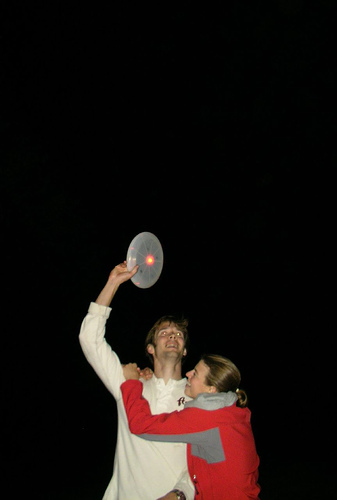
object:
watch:
[169, 486, 185, 499]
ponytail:
[235, 386, 250, 410]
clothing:
[119, 377, 262, 499]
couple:
[55, 254, 265, 500]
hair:
[201, 354, 247, 409]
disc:
[125, 230, 164, 289]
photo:
[0, 2, 336, 500]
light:
[146, 253, 154, 265]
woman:
[120, 352, 265, 500]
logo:
[176, 395, 186, 408]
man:
[76, 257, 204, 500]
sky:
[1, 0, 336, 499]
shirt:
[77, 298, 194, 499]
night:
[0, 0, 337, 500]